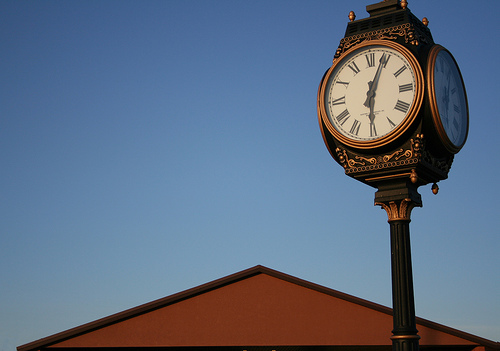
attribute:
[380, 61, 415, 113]
numerals — black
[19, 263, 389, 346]
roof — brown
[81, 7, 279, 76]
sky — blue